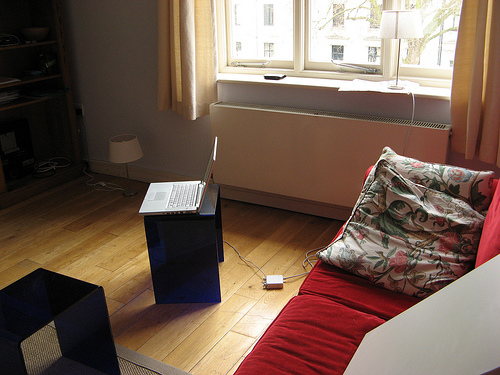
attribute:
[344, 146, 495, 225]
pillow — floral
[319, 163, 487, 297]
pillow — floral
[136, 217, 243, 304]
table — black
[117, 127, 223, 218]
laptop — gray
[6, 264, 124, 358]
stool — Black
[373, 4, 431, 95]
lamp — small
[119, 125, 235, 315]
table — blue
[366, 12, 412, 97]
lamp — small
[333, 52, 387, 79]
silver lever — Silver 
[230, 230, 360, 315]
cord — white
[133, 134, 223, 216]
laptop — silver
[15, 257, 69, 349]
table — small, dark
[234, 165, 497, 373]
sofa — red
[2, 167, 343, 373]
floor — wooden , wood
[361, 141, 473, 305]
pillows — beige, floral